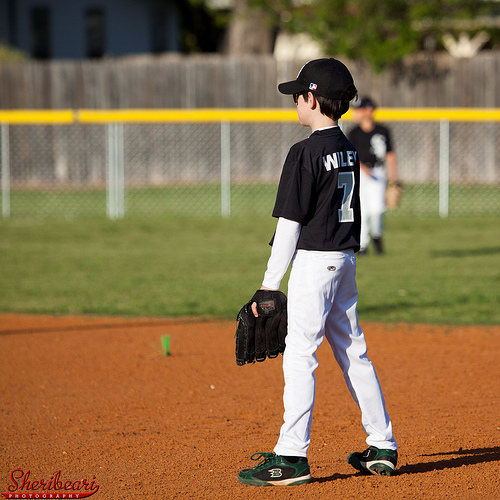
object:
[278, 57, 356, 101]
hat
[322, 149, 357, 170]
name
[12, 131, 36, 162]
square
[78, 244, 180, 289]
grass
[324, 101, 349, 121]
hair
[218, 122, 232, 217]
pole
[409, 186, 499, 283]
green grass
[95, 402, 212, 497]
section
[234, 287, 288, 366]
baseball glove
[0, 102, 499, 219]
fence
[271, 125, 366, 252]
jersey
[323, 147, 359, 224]
writing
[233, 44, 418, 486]
boy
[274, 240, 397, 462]
pants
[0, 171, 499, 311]
turf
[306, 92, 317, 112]
ear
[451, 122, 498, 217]
square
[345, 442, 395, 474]
shoe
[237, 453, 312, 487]
shoe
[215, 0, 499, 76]
leaves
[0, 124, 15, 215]
pole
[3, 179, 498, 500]
field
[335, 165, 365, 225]
number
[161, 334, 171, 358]
ball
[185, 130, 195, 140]
square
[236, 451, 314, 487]
cleats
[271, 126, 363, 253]
shirt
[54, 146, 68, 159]
square